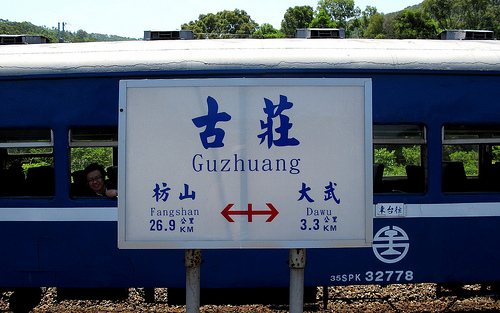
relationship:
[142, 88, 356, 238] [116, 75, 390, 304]
writing on sign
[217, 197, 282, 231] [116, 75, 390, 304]
arrows on sign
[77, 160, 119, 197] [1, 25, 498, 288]
person on train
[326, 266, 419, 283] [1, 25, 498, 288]
number printed on train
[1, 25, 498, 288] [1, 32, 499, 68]
train has roof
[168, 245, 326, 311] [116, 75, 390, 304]
poles holding sign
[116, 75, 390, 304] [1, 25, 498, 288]
sign near train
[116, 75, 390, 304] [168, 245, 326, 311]
sign on poles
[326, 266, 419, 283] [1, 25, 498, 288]
number on train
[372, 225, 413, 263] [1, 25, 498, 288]
logo on train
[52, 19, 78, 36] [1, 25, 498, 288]
business behind train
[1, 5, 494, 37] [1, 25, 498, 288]
trees behind train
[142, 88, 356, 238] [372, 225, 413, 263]
writing above logo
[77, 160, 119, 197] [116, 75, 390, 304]
person near sign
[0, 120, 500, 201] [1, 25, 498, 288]
windows on train